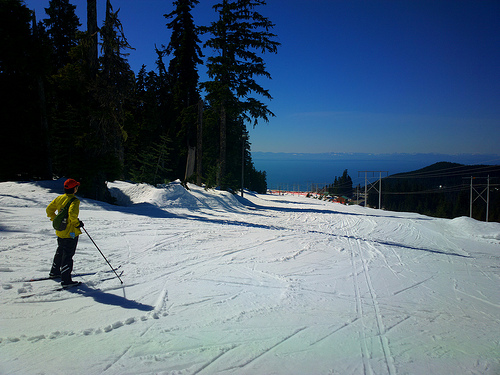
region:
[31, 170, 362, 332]
a skier in a snow field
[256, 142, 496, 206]
mountains on the background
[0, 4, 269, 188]
green trees on left side of field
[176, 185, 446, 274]
shadows cast on snow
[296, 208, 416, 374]
marks of skis on the snow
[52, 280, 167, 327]
shadow of a person on snow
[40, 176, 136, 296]
person holding a snow pole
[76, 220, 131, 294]
a black snow pole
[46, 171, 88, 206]
a red cap on a head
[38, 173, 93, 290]
person wearing a yellow coat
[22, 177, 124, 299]
skier looking down the hill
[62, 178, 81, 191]
red hat on the skier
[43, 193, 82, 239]
yellow jacket on the skier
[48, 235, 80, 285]
black pants on the skier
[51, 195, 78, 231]
black bag on the skier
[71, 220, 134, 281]
ski pole held by the skier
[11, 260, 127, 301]
skies on the feet of the person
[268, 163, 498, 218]
power lines running along the hill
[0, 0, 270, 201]
green trees on the side of the hill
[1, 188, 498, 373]
tracks left in the snow by skiers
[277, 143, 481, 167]
a distant mountain range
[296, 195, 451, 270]
a few sets of tracks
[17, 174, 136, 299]
a skiier enjoying the view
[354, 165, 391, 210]
a pair of posts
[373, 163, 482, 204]
a few electrical wires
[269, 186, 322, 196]
a bright orange fence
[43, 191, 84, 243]
a neon yellow jacket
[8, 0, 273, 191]
a forest of tall trees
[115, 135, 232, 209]
a tree lined snow bank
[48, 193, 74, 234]
a dark green bag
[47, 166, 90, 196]
person has red hat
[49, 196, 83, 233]
person has yellow coat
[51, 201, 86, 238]
black bag on back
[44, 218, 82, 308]
person has black pants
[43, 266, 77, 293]
person has black boots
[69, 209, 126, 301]
person holds ski pole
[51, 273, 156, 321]
person casts shadow on snow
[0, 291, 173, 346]
tracks dug in snow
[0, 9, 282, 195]
tall pine trees near person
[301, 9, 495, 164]
sky is deep blue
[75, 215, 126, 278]
Ski stick in person's hand.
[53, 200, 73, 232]
Bag on the person's back.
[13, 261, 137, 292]
Two skis in the snow.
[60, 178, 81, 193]
Red hat on person's head.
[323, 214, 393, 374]
Tracks of skis in the snow.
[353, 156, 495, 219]
Ski lines in the far distance.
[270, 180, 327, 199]
Orange tape for ski lines.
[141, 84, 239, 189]
Group of trees to the left.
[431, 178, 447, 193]
Small light in the mountain.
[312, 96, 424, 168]
Blue horizon on the other side.